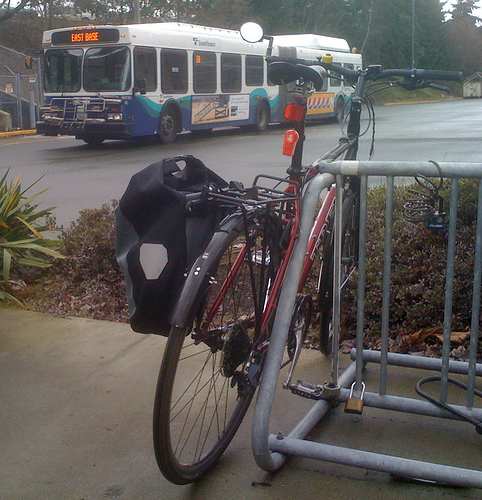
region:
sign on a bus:
[50, 27, 121, 45]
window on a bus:
[43, 51, 77, 93]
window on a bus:
[85, 44, 137, 93]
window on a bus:
[131, 31, 162, 98]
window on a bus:
[187, 46, 219, 95]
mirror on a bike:
[229, 21, 272, 47]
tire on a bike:
[136, 331, 190, 460]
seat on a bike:
[253, 48, 335, 100]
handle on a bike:
[366, 48, 464, 88]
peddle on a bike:
[290, 372, 329, 409]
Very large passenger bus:
[30, 18, 366, 147]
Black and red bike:
[109, 17, 466, 490]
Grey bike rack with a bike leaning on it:
[250, 158, 480, 498]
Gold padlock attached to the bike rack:
[341, 375, 369, 418]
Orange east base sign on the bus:
[67, 28, 102, 45]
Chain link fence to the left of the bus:
[0, 41, 45, 136]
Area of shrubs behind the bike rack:
[0, 158, 476, 377]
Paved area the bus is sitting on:
[0, 94, 479, 242]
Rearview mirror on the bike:
[237, 18, 274, 62]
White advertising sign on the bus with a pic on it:
[186, 90, 254, 129]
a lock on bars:
[318, 354, 402, 438]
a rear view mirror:
[227, 14, 306, 77]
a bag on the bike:
[93, 149, 245, 370]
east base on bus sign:
[54, 16, 125, 53]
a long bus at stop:
[35, 24, 408, 147]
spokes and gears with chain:
[209, 324, 262, 390]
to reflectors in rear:
[260, 100, 321, 172]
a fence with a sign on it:
[1, 58, 30, 146]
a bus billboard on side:
[182, 90, 261, 132]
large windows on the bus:
[191, 38, 224, 99]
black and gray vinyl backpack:
[109, 151, 243, 347]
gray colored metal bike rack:
[246, 149, 480, 498]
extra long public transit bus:
[32, 16, 368, 150]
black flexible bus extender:
[269, 38, 307, 128]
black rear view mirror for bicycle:
[235, 16, 279, 65]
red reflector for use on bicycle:
[280, 95, 310, 125]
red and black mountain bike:
[144, 16, 467, 492]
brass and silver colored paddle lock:
[340, 379, 366, 417]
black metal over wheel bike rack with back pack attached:
[194, 171, 308, 350]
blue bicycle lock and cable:
[395, 155, 450, 239]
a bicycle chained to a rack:
[153, 20, 459, 485]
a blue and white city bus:
[32, 17, 372, 148]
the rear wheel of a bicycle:
[147, 223, 292, 488]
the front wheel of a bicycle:
[320, 191, 357, 361]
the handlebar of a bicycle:
[373, 51, 465, 93]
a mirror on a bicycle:
[238, 18, 268, 48]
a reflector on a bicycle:
[284, 102, 308, 124]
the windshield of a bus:
[45, 49, 128, 93]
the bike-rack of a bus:
[38, 100, 114, 130]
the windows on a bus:
[133, 45, 267, 96]